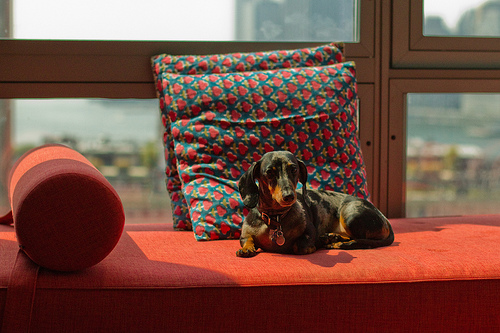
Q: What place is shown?
A: It is a city.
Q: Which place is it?
A: It is a city.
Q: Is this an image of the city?
A: Yes, it is showing the city.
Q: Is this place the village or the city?
A: It is the city.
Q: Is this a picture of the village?
A: No, the picture is showing the city.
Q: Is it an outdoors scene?
A: Yes, it is outdoors.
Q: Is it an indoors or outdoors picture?
A: It is outdoors.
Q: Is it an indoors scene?
A: No, it is outdoors.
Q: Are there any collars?
A: Yes, there is a collar.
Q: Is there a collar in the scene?
A: Yes, there is a collar.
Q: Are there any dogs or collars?
A: Yes, there is a collar.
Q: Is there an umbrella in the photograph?
A: No, there are no umbrellas.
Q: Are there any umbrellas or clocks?
A: No, there are no umbrellas or clocks.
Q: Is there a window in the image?
A: Yes, there is a window.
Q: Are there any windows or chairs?
A: Yes, there is a window.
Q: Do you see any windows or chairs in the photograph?
A: Yes, there is a window.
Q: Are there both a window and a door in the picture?
A: No, there is a window but no doors.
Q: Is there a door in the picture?
A: No, there are no doors.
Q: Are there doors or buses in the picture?
A: No, there are no doors or buses.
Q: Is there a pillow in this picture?
A: Yes, there is a pillow.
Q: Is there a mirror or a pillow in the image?
A: Yes, there is a pillow.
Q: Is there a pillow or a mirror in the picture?
A: Yes, there is a pillow.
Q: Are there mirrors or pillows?
A: Yes, there is a pillow.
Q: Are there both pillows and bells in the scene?
A: No, there is a pillow but no bells.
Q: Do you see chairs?
A: No, there are no chairs.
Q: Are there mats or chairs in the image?
A: No, there are no chairs or mats.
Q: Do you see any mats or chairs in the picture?
A: No, there are no chairs or mats.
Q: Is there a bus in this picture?
A: No, there are no buses.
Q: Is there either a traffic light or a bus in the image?
A: No, there are no buses or traffic lights.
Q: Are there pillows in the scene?
A: Yes, there is a pillow.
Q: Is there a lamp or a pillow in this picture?
A: Yes, there is a pillow.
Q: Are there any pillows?
A: Yes, there is a pillow.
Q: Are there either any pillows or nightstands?
A: Yes, there is a pillow.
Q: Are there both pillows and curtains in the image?
A: No, there is a pillow but no curtains.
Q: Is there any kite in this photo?
A: No, there are no kites.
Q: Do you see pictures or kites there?
A: No, there are no kites or pictures.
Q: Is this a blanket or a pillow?
A: This is a pillow.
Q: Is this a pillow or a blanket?
A: This is a pillow.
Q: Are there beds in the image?
A: Yes, there is a bed.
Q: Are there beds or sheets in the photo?
A: Yes, there is a bed.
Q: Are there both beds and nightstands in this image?
A: No, there is a bed but no nightstands.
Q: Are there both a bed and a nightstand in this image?
A: No, there is a bed but no nightstands.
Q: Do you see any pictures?
A: No, there are no pictures.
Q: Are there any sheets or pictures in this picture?
A: No, there are no pictures or sheets.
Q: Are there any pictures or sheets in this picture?
A: No, there are no pictures or sheets.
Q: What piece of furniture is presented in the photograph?
A: The piece of furniture is a bed.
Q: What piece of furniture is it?
A: The piece of furniture is a bed.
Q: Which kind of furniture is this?
A: This is a bed.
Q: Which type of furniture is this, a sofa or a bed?
A: This is a bed.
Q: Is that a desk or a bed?
A: That is a bed.